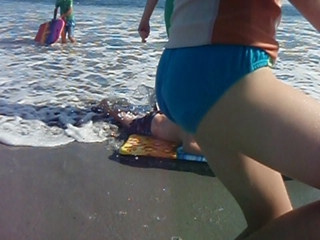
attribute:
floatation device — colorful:
[118, 129, 198, 177]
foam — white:
[0, 112, 109, 147]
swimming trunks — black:
[59, 19, 77, 39]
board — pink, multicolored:
[33, 14, 70, 63]